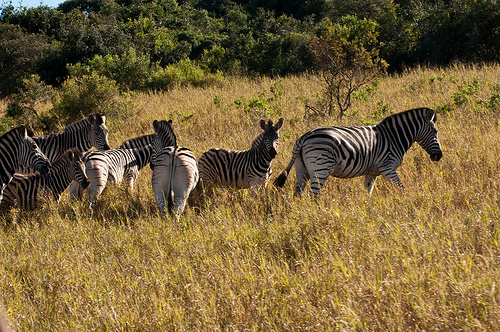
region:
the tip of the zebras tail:
[275, 168, 291, 192]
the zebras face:
[419, 120, 452, 157]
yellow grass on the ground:
[178, 266, 465, 326]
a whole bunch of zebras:
[19, 117, 495, 205]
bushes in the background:
[24, 5, 416, 77]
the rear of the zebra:
[170, 152, 200, 206]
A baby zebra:
[27, 156, 102, 207]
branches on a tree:
[317, 60, 375, 124]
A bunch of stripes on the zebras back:
[36, 126, 78, 152]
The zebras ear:
[255, 114, 268, 127]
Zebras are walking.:
[3, 113, 449, 208]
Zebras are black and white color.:
[16, 121, 396, 179]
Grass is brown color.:
[123, 229, 422, 308]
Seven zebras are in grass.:
[11, 110, 439, 212]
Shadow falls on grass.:
[12, 180, 385, 232]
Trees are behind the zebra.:
[23, 45, 471, 81]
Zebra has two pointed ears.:
[250, 107, 291, 127]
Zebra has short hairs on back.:
[375, 100, 421, 130]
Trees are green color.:
[60, 21, 230, 52]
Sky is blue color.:
[8, 0, 70, 12]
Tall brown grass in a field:
[168, 275, 265, 322]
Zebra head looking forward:
[255, 117, 281, 157]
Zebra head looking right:
[414, 102, 444, 164]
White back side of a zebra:
[155, 158, 190, 196]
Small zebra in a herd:
[6, 150, 97, 209]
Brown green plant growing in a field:
[58, 77, 124, 108]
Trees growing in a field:
[3, 15, 128, 65]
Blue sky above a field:
[0, 0, 80, 19]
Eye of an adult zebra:
[32, 142, 38, 150]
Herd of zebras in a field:
[1, 104, 466, 212]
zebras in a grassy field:
[4, 96, 459, 237]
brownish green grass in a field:
[15, 225, 487, 315]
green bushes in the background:
[37, 11, 462, 60]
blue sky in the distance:
[2, 0, 60, 5]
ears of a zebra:
[254, 113, 287, 140]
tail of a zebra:
[272, 146, 299, 203]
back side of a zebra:
[143, 144, 214, 226]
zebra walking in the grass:
[276, 104, 451, 214]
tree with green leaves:
[292, 11, 404, 112]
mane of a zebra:
[369, 107, 441, 128]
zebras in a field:
[21, 35, 442, 252]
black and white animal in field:
[317, 104, 444, 201]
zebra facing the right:
[274, 98, 455, 237]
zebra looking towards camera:
[211, 111, 290, 211]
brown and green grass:
[227, 217, 372, 307]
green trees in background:
[128, 6, 243, 70]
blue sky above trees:
[11, 1, 58, 18]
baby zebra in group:
[14, 156, 94, 213]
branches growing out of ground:
[303, 48, 378, 119]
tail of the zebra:
[268, 153, 309, 198]